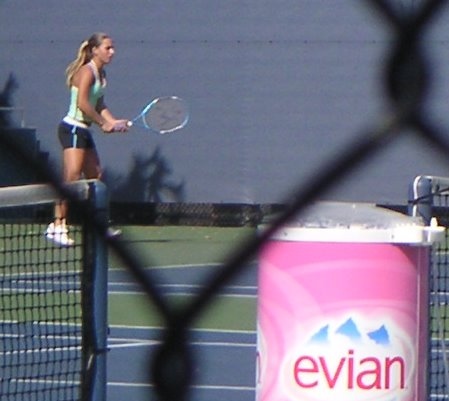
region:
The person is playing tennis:
[44, 32, 188, 244]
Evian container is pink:
[256, 198, 429, 400]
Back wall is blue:
[0, 1, 448, 221]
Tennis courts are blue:
[0, 221, 447, 399]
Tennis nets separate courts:
[0, 175, 448, 399]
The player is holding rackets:
[44, 33, 188, 244]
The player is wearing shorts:
[44, 31, 190, 247]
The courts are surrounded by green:
[1, 223, 448, 340]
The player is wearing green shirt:
[42, 32, 188, 246]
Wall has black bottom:
[0, 202, 447, 231]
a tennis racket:
[113, 96, 190, 133]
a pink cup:
[251, 217, 417, 398]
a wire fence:
[2, 1, 443, 398]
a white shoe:
[41, 219, 76, 249]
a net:
[2, 200, 110, 399]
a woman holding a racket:
[49, 26, 192, 249]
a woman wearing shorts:
[36, 31, 134, 248]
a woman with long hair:
[44, 30, 131, 247]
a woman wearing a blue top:
[42, 28, 136, 255]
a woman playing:
[35, 23, 187, 245]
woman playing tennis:
[43, 24, 191, 252]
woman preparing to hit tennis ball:
[34, 25, 195, 253]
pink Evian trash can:
[243, 215, 436, 399]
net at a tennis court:
[0, 176, 118, 397]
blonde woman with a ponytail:
[61, 25, 122, 92]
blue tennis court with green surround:
[150, 219, 239, 311]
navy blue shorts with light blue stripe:
[55, 117, 103, 153]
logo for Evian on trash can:
[289, 343, 412, 394]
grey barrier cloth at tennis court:
[188, 4, 325, 199]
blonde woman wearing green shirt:
[62, 27, 128, 139]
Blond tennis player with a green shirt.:
[42, 16, 131, 254]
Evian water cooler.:
[243, 190, 432, 399]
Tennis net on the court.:
[1, 164, 113, 396]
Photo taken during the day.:
[5, 11, 434, 394]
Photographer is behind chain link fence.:
[10, 3, 431, 394]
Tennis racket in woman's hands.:
[97, 79, 216, 147]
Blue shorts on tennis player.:
[48, 111, 97, 154]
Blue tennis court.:
[3, 245, 447, 296]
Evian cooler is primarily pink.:
[246, 227, 446, 398]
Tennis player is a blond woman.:
[40, 22, 140, 252]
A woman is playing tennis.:
[40, 25, 209, 262]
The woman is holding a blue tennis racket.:
[76, 27, 198, 143]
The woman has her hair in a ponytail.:
[53, 23, 120, 85]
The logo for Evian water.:
[277, 315, 420, 390]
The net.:
[1, 161, 132, 393]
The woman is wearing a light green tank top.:
[44, 14, 128, 248]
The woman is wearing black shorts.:
[25, 10, 146, 172]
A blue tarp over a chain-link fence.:
[124, 26, 243, 224]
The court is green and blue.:
[113, 236, 226, 381]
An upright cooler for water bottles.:
[227, 199, 443, 390]